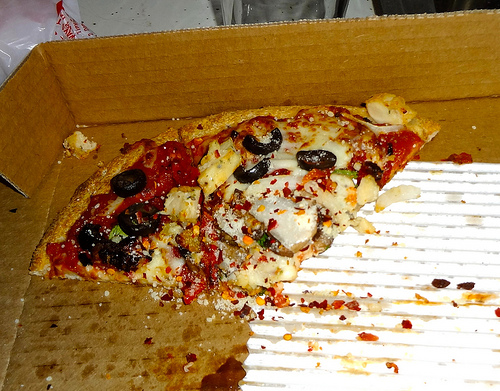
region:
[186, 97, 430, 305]
slice of pizza with olives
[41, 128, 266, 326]
slice of pizza with olives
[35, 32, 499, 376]
cardboard container with pizza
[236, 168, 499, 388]
white cardboard liner in box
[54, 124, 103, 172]
crumb of pizza in box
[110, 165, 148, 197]
black round olive slice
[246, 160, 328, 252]
piece of mozzarella cheese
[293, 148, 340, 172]
black olive on white cheese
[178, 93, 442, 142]
golden baked crust of pizza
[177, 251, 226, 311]
tomatoes on pizza slice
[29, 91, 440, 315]
Partially left over pizza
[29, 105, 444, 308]
Less than half a pizza remaining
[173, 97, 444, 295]
Pizza slize with olives and pineapple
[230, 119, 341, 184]
Sliced black olives on pizza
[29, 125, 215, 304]
Pizza sauce mixed with cheese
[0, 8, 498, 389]
Oppened cardboard box containing pizza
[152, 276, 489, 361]
Pizza leftover crumbs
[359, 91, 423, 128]
Slice of mushroom on pizza edge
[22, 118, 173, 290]
Dark brown pizza crust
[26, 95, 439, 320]
Two vegetable pizza slices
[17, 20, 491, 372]
Some pizza in a cardboard box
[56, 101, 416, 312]
Two slices of pizza in the cardboard box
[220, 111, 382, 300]
The pizza has many toppings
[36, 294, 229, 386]
The cardboard box is dirty and stained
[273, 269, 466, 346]
Bits of pizza on the white paper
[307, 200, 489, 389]
White paper below the pizza in the box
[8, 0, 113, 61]
A white plastic bag behind the pizza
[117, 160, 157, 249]
Black olives on top of the pizza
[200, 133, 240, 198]
A chunk of chicken on the pizza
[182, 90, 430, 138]
A thin pizza crust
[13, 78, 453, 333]
A pizza in the foreground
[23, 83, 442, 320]
Two pizza slices in the foreground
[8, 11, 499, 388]
Pizza is inside a box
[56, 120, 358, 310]
Pizza has black olives as a topping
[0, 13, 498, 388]
Pizza box is brown in color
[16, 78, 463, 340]
Pizza slices are fully cooked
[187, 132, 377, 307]
Multiple toppings are on top of pizza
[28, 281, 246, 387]
Pizza grease is on the box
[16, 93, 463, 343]
Pizza is in the shape of a triangle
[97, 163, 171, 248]
Black olives are circular in shape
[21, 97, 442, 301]
Two slices of pizza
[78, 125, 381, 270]
Olives are on the pizza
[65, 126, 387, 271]
Black olives are on the pizza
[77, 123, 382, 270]
Sliced black olives are on the pizza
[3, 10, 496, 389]
Pizza is in a box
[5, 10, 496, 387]
Pizza in a cardboard box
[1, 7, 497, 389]
Pizza in a pizza box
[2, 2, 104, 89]
Plastic bag on the counter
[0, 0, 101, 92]
White plastic bag on counter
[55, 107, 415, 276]
Tomato sauce on pizza